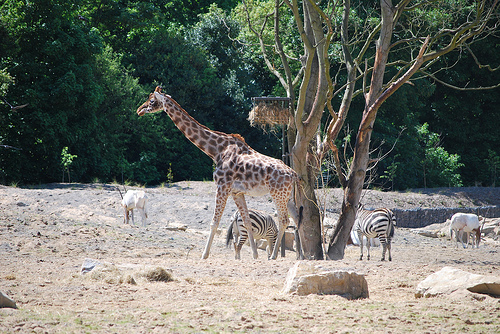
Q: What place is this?
A: It is a zoo.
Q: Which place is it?
A: It is a zoo.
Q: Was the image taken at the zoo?
A: Yes, it was taken in the zoo.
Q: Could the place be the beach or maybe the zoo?
A: It is the zoo.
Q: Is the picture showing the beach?
A: No, the picture is showing the zoo.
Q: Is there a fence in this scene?
A: No, there are no fences.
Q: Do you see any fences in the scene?
A: No, there are no fences.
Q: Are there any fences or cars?
A: No, there are no fences or cars.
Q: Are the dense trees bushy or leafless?
A: The trees are bushy.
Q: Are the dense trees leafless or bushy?
A: The trees are bushy.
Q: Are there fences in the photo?
A: No, there are no fences.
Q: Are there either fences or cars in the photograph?
A: No, there are no fences or cars.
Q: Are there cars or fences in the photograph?
A: No, there are no fences or cars.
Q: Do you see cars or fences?
A: No, there are no fences or cars.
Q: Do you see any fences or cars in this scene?
A: No, there are no fences or cars.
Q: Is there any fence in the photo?
A: No, there are no fences.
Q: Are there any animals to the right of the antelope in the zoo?
A: Yes, there are animals to the right of the antelope.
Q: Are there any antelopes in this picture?
A: Yes, there is an antelope.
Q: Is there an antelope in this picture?
A: Yes, there is an antelope.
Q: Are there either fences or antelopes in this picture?
A: Yes, there is an antelope.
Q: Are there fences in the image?
A: No, there are no fences.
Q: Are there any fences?
A: No, there are no fences.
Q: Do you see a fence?
A: No, there are no fences.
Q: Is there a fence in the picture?
A: No, there are no fences.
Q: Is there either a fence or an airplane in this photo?
A: No, there are no fences or airplanes.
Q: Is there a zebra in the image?
A: Yes, there is a zebra.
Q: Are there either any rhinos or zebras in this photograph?
A: Yes, there is a zebra.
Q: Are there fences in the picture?
A: No, there are no fences.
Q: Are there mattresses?
A: No, there are no mattresses.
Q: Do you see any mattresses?
A: No, there are no mattresses.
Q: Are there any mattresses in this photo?
A: No, there are no mattresses.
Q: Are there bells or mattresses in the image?
A: No, there are no mattresses or bells.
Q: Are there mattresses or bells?
A: No, there are no mattresses or bells.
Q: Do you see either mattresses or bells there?
A: No, there are no mattresses or bells.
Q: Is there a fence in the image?
A: No, there are no fences.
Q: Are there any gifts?
A: No, there are no gifts.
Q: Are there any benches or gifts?
A: No, there are no gifts or benches.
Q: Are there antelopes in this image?
A: Yes, there is an antelope.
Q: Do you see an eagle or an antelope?
A: Yes, there is an antelope.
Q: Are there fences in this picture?
A: No, there are no fences.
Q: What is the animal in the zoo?
A: The animal is an antelope.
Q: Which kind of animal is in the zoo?
A: The animal is an antelope.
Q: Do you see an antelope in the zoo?
A: Yes, there is an antelope in the zoo.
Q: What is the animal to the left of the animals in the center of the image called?
A: The animal is an antelope.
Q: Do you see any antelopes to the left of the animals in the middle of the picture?
A: Yes, there is an antelope to the left of the animals.